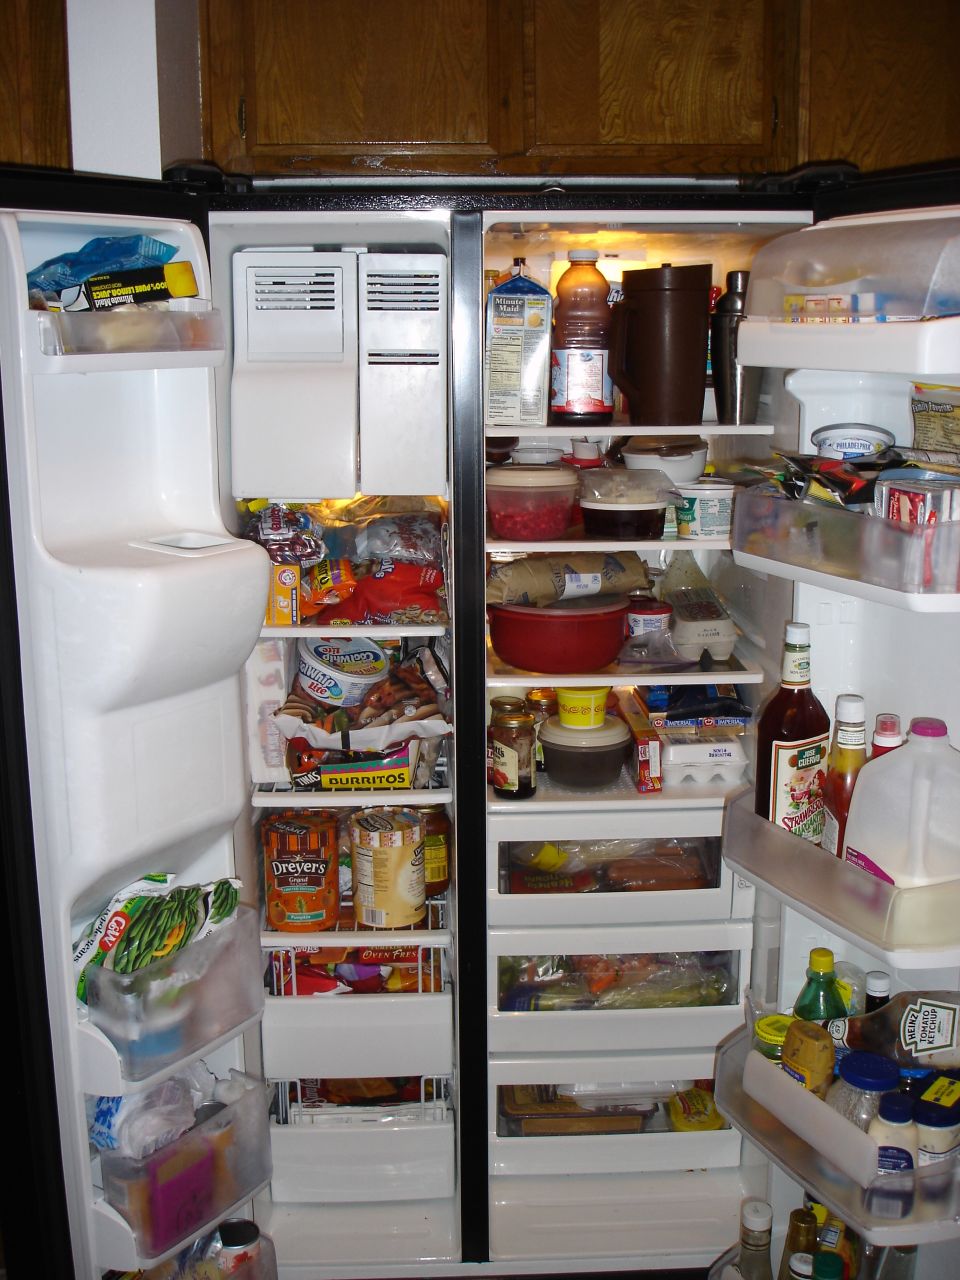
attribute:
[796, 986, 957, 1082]
ketchup — on side, bottle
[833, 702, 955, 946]
milk — gallon, half full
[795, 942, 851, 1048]
lemon juice — bottle